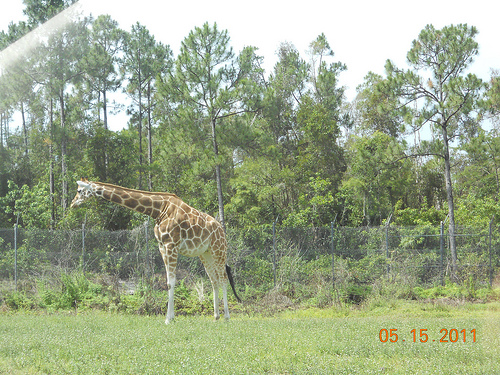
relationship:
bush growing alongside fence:
[0, 252, 479, 309] [8, 222, 497, 302]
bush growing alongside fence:
[337, 260, 375, 308] [8, 222, 497, 302]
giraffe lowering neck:
[68, 171, 248, 323] [90, 177, 170, 217]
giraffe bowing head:
[68, 171, 248, 323] [68, 174, 92, 209]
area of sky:
[0, 33, 500, 375] [153, 4, 463, 51]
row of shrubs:
[22, 259, 466, 292] [266, 255, 415, 290]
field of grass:
[21, 305, 481, 366] [89, 316, 390, 359]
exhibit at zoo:
[37, 50, 457, 304] [34, 77, 426, 301]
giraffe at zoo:
[68, 171, 248, 323] [34, 77, 426, 301]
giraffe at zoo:
[68, 171, 248, 323] [16, 50, 480, 330]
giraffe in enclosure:
[68, 171, 248, 323] [26, 70, 447, 333]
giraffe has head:
[68, 171, 248, 323] [67, 175, 94, 212]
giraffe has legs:
[68, 171, 248, 323] [156, 248, 250, 334]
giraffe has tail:
[68, 171, 248, 323] [223, 261, 243, 306]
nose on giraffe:
[72, 206, 81, 212] [65, 185, 245, 324]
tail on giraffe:
[225, 250, 249, 307] [65, 185, 245, 324]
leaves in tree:
[0, 29, 499, 203] [0, 12, 500, 257]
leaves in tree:
[372, 179, 391, 195] [245, 100, 425, 247]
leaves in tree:
[0, 29, 499, 203] [334, 128, 444, 283]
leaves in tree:
[0, 29, 499, 203] [339, 117, 438, 276]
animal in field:
[66, 167, 253, 335] [2, 304, 481, 372]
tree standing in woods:
[0, 12, 500, 257] [1, 0, 482, 285]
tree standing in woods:
[292, 30, 352, 258] [1, 0, 482, 285]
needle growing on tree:
[229, 46, 233, 54] [0, 12, 500, 257]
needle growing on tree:
[227, 36, 230, 44] [0, 12, 500, 257]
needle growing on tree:
[204, 23, 206, 29] [0, 12, 500, 257]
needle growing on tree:
[194, 52, 195, 54] [0, 12, 500, 257]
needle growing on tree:
[183, 89, 186, 91] [0, 12, 500, 257]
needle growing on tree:
[471, 44, 474, 50] [370, 19, 483, 269]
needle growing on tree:
[452, 35, 455, 41] [370, 19, 483, 269]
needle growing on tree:
[413, 40, 415, 45] [370, 19, 483, 269]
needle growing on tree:
[407, 56, 410, 61] [370, 19, 483, 269]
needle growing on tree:
[443, 84, 444, 89] [370, 19, 483, 269]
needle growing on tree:
[100, 16, 101, 20] [82, 12, 129, 181]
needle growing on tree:
[114, 22, 115, 25] [82, 12, 129, 181]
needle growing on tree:
[105, 14, 106, 18] [82, 12, 129, 181]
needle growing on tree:
[96, 34, 97, 38] [82, 12, 129, 181]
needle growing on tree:
[108, 22, 110, 27] [82, 12, 129, 181]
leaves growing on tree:
[0, 29, 499, 203] [350, 127, 416, 236]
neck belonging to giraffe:
[90, 180, 174, 221] [68, 171, 248, 323]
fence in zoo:
[8, 222, 497, 302] [1, 153, 497, 373]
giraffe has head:
[68, 171, 248, 323] [64, 173, 105, 214]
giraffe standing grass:
[68, 171, 248, 323] [107, 330, 317, 371]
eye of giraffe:
[67, 176, 89, 195] [54, 149, 314, 373]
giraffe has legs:
[68, 171, 248, 323] [156, 239, 235, 329]